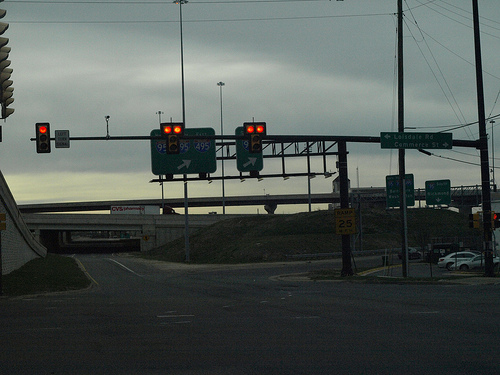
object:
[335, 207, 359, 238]
yellow sign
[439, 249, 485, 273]
car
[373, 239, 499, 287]
lot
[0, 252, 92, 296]
grass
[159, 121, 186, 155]
traffic light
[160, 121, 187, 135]
double lights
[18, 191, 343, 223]
overpass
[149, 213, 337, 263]
slope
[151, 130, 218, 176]
green signs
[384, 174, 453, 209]
traffic signs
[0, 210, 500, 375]
road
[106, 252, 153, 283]
traffic lines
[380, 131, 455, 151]
street sign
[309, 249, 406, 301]
street corner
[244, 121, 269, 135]
red traffic light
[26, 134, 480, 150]
street pole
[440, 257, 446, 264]
tail light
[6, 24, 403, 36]
electrical wires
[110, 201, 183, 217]
tractor trailer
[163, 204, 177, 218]
cab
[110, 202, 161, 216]
trailer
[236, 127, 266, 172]
traffi sign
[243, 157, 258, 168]
arrow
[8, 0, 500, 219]
sky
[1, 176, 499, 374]
traffic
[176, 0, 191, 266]
street light pole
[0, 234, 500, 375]
street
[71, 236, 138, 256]
shadow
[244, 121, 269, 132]
red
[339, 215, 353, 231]
speed limit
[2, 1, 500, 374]
bad weather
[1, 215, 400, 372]
no traffic